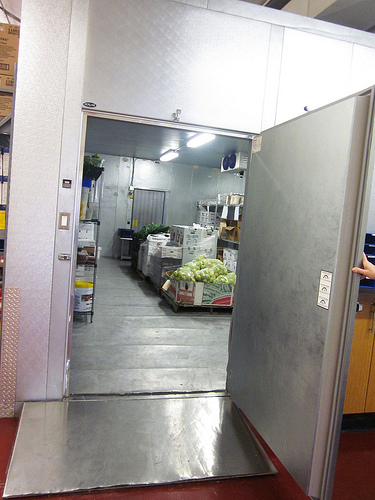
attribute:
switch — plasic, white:
[59, 208, 70, 230]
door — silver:
[224, 82, 373, 499]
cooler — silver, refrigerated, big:
[78, 104, 247, 398]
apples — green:
[165, 255, 234, 290]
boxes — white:
[172, 220, 224, 263]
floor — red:
[339, 422, 372, 497]